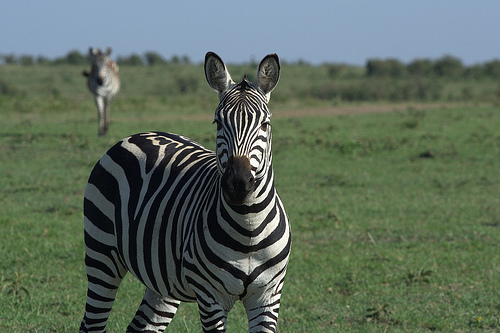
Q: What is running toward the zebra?
A: Another zebra.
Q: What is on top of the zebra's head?
A: Ears.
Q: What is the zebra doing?
A: Looking at the camera.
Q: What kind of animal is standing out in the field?
A: A zebra.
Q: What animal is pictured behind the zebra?
A: Another zebra.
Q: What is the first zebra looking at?
A: At the camera.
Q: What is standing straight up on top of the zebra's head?
A: The zebra's ears.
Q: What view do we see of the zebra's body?
A: We see the side view of the zebra.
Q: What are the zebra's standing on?
A: The zebra is standing on top of grass out in a field.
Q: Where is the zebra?
A: The zebra's are outside.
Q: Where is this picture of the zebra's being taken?
A: This picture was taken outside out in a field.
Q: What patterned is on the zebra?
A: This zebra has a striped pattern.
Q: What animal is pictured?
A: Zebra.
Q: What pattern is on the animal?
A: Stripes.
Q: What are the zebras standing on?
A: Grass.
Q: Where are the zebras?
A: A field.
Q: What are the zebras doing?
A: Walking.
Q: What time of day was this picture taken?
A: The day.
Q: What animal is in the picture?
A: Zebra.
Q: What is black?
A: Stripes.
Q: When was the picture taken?
A: Daytime.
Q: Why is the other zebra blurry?
A: Out of focus.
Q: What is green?
A: Grass.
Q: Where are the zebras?
A: Field.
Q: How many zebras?
A: Two.